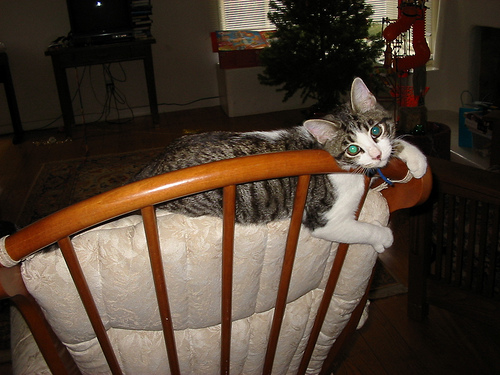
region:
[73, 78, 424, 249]
cat with green eyes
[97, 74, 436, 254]
cat sitting on a chair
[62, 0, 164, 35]
TV sitting on stand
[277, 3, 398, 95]
Christmas tree with no decorations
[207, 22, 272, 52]
wrapped gift on table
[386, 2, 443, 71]
two red long stockings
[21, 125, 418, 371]
wood chair with beige cushions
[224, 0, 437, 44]
window with mini blinds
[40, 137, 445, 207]
area rug on carpet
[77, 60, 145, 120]
cords hanging from TV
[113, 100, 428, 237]
A white and grey cat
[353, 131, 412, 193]
The cat's collar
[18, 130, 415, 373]
A wooden chair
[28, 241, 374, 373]
A white cushion on the chair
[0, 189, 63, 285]
strap attaching the cushion to the chair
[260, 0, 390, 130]
A pine tree in front of the window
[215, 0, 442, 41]
A window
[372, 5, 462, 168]
A cat play tower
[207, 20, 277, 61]
A colorful gift bag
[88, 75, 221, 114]
electrical cords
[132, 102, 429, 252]
Cat siting on chair.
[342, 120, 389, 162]
Cat's eyes appear green.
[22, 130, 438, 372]
Chair is made of wood.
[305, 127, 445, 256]
Cat has white paws.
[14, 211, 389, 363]
Chair cushion is beige.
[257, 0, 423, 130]
Christmas tree in the background.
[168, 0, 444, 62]
The blinds are drawn.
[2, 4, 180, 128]
Tv on a stand.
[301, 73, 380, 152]
Cat's ears are alert.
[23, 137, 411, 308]
Area rug located on the floor.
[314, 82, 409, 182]
Cat looking at the camera.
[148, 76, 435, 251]
Cat on the chair.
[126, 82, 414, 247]
Cat is a grey and white tiger.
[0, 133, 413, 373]
Chair is made of wood.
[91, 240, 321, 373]
Cushion on the chair.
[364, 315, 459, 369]
The floor is wooden.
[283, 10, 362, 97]
A Christmas tree in the background.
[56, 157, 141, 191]
A rug on the floor.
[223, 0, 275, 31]
A window behind the tree.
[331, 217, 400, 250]
The front leg is white.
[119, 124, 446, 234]
cat laying down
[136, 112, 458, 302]
cat laying on chair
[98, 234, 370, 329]
white pad on chair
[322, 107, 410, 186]
cat with blue eyes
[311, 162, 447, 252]
cat with white paws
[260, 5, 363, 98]
christmas tree in the background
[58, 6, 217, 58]
tv in the background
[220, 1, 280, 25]
blinds on the window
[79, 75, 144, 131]
wire under table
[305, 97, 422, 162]
cat with ears sticking up